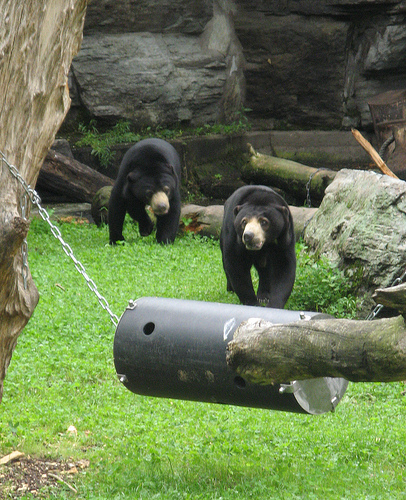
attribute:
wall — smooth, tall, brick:
[91, 0, 403, 120]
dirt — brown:
[3, 410, 118, 498]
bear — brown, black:
[219, 176, 301, 308]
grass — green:
[7, 207, 397, 490]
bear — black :
[88, 97, 225, 251]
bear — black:
[227, 182, 290, 306]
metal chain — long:
[0, 150, 117, 329]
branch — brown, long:
[350, 126, 397, 178]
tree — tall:
[0, 0, 88, 399]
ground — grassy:
[180, 422, 195, 445]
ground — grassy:
[1, 217, 404, 497]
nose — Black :
[240, 227, 257, 243]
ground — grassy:
[90, 434, 335, 492]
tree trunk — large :
[1, 4, 86, 372]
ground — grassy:
[111, 413, 402, 498]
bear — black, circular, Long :
[219, 184, 296, 307]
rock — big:
[298, 164, 404, 321]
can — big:
[115, 296, 349, 414]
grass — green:
[127, 413, 393, 491]